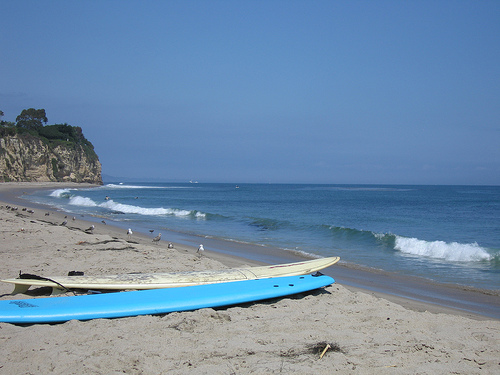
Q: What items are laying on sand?
A: Surfboards.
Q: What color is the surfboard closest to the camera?
A: Blue.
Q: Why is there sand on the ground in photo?
A: It's a beach.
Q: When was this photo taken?
A: Daytime.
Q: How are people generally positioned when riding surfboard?
A: Standing.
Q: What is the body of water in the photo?
A: Ocean.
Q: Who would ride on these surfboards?
A: Surfers.